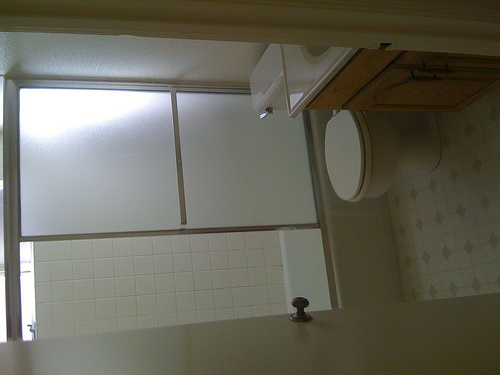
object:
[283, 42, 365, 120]
sink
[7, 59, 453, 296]
window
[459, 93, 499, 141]
flooring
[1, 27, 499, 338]
bathroom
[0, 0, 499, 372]
photo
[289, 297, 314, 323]
handle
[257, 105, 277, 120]
handle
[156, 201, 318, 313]
wall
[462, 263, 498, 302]
floor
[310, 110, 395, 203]
bowl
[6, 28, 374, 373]
sliding shower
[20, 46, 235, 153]
window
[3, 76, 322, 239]
frame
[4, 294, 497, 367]
door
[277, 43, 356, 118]
vanity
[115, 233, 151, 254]
white tile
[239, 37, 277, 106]
sink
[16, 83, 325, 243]
door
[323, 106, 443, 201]
toilet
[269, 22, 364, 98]
sink top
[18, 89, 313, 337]
shwer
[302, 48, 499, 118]
cabinet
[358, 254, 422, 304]
pattern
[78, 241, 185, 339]
wall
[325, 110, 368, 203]
cover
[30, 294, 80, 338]
tile